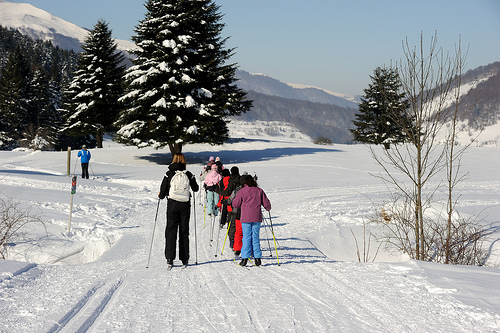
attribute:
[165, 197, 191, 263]
pants — black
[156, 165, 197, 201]
jacket — black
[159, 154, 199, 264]
woman — skiing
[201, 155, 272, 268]
people — skiing, lined, young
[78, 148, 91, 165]
jacket — blue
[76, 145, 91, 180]
man — alone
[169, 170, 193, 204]
backpack — white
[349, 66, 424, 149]
tree — green, pine, snow covered, large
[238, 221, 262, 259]
pants — blue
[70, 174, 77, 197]
sign — green, red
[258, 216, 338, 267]
shadows — people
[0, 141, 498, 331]
snow — white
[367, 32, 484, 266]
bush — bare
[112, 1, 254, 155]
tree — green, snow covered, large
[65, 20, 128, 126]
tree — green, snow covered, large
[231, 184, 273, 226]
jacket — purple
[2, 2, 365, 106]
snow — white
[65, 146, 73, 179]
pole — colorful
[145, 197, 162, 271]
ski pole — black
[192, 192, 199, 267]
ski pole — black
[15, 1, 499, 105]
sky — overcast, gray